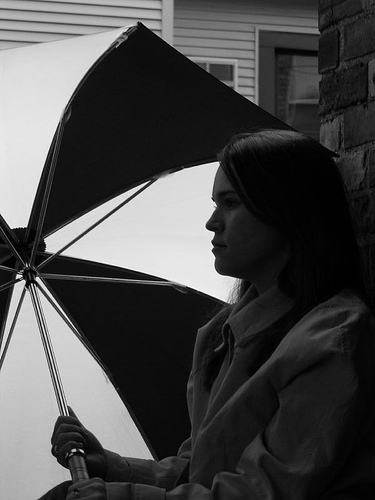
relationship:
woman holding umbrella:
[41, 129, 374, 484] [0, 20, 336, 497]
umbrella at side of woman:
[0, 20, 336, 497] [41, 129, 374, 484]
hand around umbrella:
[48, 408, 149, 484] [0, 20, 336, 497]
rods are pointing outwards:
[0, 115, 172, 364] [0, 21, 347, 145]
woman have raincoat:
[41, 129, 374, 484] [180, 285, 362, 500]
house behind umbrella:
[1, 6, 370, 111] [0, 20, 336, 497]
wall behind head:
[314, 8, 373, 217] [207, 137, 349, 291]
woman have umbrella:
[41, 129, 374, 484] [0, 20, 336, 497]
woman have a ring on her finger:
[41, 129, 374, 484] [48, 431, 59, 448]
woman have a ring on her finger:
[41, 129, 374, 484] [54, 453, 65, 464]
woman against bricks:
[41, 129, 374, 484] [317, 12, 373, 202]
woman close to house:
[41, 129, 374, 484] [1, 6, 370, 111]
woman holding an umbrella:
[41, 129, 374, 484] [0, 20, 336, 497]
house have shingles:
[1, 6, 370, 111] [1, 0, 321, 25]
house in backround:
[1, 6, 370, 111] [4, 9, 372, 152]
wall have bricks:
[314, 8, 373, 217] [317, 12, 373, 202]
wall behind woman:
[314, 8, 373, 217] [41, 129, 374, 484]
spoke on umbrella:
[11, 132, 103, 485] [0, 20, 336, 497]